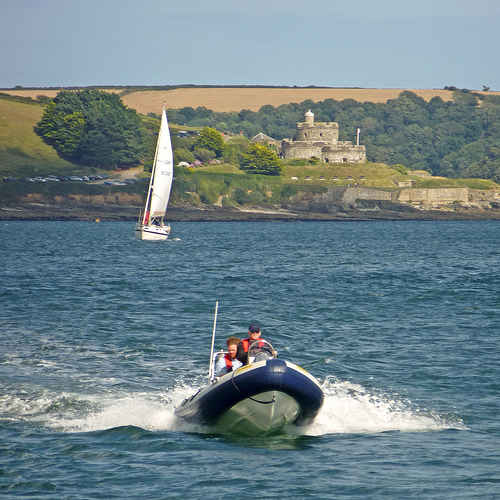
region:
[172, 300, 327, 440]
a boat with two people in it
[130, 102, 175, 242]
a sailboat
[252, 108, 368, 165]
an old stone building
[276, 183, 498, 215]
a stone wall along the edge of the water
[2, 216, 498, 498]
a calm blue body of water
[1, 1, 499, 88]
a cloudless blue sky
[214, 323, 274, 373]
two people wearing orange life vests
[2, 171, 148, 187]
cars parked on the street in the background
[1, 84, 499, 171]
green rolling hills in the background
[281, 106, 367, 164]
a stone castle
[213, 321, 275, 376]
people riding in a boat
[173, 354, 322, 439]
a small motorboat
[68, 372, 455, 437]
waves behind the boat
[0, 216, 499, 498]
choppy blue water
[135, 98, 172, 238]
a sailboat on the water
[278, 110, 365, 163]
a castle on the hill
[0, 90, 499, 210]
a grassy hill in the background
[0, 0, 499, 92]
a clear blue sky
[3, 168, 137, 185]
cars parked on the hill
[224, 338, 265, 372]
orange life vests on the people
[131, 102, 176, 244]
The sail boat is white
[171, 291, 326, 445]
The speed boat is blue and white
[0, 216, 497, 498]
The water is choppy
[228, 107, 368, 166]
The castle is old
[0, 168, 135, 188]
Cars are parked on the hill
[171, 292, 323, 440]
The closest boat has two people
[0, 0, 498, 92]
The sky is clear and grayish blue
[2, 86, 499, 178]
The farthest hill is covered in trees and farmland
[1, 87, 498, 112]
The farmland is yellow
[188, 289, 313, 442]
The driver of the closest boat is wearing a hat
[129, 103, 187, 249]
A PHOTO OF A SAILBOAT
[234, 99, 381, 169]
A PHOTO OF A BUILDING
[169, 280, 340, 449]
TWO PEOPLE IN A MOTORBOAT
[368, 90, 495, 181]
TREES IN THE DISTANCE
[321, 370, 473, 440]
BREAKING WATER FROM THE BOAT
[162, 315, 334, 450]
A BLUE AND WHITE BOAT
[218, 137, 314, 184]
A BUSH IN THE BACKGROUND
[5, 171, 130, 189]
CARS PARKED IN THE DISTANCE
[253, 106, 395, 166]
A STONE BUILDING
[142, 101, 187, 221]
A WHITE SALE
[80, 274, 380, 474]
speed boat in water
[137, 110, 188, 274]
sail boat in water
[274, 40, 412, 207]
castle overlookng water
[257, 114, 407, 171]
castle in photograph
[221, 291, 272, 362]
person driving boat wears hat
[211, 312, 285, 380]
two people with orange life jackets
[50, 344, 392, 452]
waves from speed boat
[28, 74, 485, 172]
trees in background with castle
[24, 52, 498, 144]
fields in background of photo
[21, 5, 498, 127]
blue sky in photo